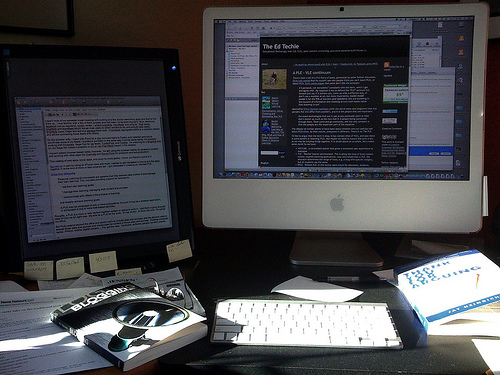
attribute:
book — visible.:
[392, 247, 498, 337]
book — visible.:
[49, 281, 209, 372]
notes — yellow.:
[22, 238, 194, 280]